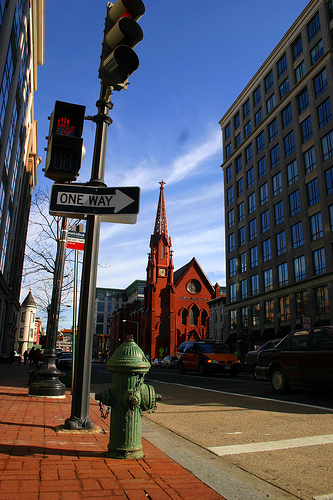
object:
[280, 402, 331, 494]
street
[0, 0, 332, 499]
city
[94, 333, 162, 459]
fire hydrant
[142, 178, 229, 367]
building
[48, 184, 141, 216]
sign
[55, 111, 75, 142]
light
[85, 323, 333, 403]
traffic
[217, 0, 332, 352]
building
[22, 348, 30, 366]
person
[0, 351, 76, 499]
sidewalk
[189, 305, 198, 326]
window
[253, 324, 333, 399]
car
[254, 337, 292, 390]
rear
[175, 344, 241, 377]
minivan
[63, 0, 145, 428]
pole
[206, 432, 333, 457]
line